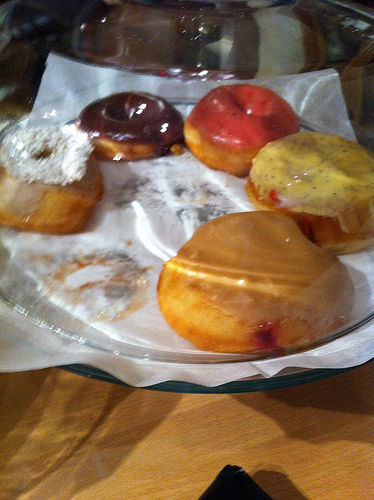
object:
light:
[134, 99, 147, 117]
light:
[159, 121, 171, 133]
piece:
[244, 130, 374, 251]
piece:
[181, 79, 301, 178]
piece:
[77, 89, 184, 162]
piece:
[0, 122, 104, 236]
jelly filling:
[253, 318, 281, 349]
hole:
[254, 320, 283, 352]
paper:
[0, 52, 374, 389]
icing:
[248, 130, 374, 216]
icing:
[77, 90, 185, 142]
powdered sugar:
[0, 122, 101, 190]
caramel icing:
[156, 208, 356, 355]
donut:
[156, 208, 354, 358]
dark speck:
[310, 183, 317, 193]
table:
[0, 0, 374, 498]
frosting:
[185, 84, 300, 152]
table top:
[0, 366, 374, 499]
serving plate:
[0, 94, 374, 394]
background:
[0, 0, 374, 499]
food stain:
[74, 251, 91, 274]